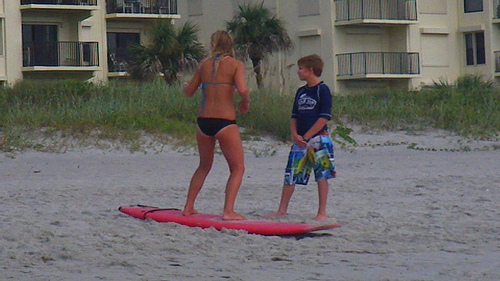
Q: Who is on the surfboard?
A: Girl in a bikini.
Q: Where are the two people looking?
A: Toward the building.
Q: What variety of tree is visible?
A: Palm.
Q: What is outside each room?
A: Balcony.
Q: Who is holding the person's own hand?
A: Boy in blue shirt.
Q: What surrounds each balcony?
A: Black railing.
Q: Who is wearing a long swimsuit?
A: Boy in blue shirt.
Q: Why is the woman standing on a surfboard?
A: Teaching boy how to surf.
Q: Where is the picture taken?
A: Beach.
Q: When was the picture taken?
A: Summer.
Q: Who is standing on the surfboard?
A: The woman in a bikini.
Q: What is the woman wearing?
A: Bikini.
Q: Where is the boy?
A: On the sand.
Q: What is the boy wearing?
A: T-shirt and shorts.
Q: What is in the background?
A: Apartments.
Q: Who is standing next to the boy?
A: A female.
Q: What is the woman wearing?
A: A bikini.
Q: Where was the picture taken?
A: By the seaside.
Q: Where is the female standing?
A: On a surfboard.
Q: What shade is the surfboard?
A: The surfboard is red.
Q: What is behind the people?
A: Apartment buildings.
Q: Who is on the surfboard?
A: A lady is.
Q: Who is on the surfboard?
A: A lady in black bikini.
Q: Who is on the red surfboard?
A: A lady next to a boy.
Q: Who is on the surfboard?
A: A lady on the beach.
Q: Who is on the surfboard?
A: A blonde haired lady.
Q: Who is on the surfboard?
A: A lady is standing on the board.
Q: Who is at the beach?
A: A girl next to a boy.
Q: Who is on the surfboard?
A: Girl.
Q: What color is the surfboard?
A: Red.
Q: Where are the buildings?
A: Background.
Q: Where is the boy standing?
A: Sand.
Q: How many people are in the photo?
A: Two.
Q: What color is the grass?
A: Green.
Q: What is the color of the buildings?
A: Beige.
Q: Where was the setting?
A: Beach.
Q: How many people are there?
A: Two.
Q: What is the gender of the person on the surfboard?
A: Female.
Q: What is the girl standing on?
A: A surfboard.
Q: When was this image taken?
A: Daytime.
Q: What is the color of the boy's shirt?
A: Blue.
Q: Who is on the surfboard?
A: The girl.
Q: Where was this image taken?
A: On a beach.